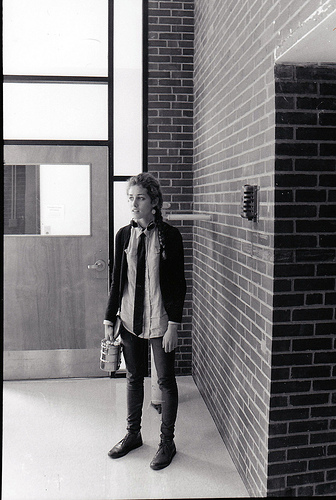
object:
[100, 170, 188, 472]
girl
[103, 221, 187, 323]
jacket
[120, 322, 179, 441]
jeans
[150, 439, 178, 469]
boot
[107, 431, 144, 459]
boot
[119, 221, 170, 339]
shirt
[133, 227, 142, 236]
collar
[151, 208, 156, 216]
earring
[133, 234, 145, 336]
tie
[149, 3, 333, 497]
wall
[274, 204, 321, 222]
brick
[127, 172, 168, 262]
hair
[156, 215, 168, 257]
braid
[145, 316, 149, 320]
button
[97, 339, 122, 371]
object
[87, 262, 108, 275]
handle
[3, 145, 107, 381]
door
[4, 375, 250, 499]
floor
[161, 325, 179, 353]
hand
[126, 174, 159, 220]
head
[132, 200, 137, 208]
nose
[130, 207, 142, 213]
mouth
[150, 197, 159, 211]
ear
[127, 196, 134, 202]
eye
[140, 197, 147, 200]
eye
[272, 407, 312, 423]
brick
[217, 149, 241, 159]
brick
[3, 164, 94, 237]
window